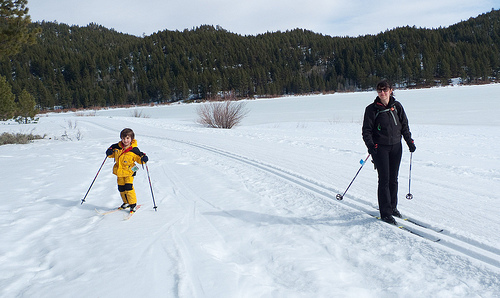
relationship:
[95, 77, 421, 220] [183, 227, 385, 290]
people in snow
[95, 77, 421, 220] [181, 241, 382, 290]
people in snow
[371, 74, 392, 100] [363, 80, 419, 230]
head on person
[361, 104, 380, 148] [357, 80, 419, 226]
arm on person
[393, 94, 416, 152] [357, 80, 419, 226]
arm on person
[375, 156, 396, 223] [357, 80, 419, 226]
leg on person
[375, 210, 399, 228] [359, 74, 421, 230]
feet on person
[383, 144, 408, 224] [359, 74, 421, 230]
leg on person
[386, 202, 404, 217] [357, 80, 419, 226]
feet on person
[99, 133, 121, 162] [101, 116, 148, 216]
arm on person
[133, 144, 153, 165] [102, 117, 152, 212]
arm on person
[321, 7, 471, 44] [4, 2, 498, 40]
clouds in sky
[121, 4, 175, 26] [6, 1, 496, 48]
clouds in sky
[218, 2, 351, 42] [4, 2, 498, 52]
clouds in sky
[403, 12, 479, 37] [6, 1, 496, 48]
clouds in sky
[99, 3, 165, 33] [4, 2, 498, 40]
clouds in sky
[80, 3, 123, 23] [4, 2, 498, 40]
clouds in sky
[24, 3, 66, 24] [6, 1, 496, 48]
clouds in sky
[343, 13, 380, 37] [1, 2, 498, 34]
clouds in sky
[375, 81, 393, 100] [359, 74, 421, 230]
head on person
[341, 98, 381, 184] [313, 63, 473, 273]
arm of person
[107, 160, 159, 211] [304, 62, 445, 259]
leg of person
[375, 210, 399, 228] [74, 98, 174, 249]
feet of person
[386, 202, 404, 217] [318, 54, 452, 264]
feet of person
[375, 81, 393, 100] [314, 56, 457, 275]
head of person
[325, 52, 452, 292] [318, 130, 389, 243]
person on ski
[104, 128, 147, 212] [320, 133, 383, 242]
boy on ski